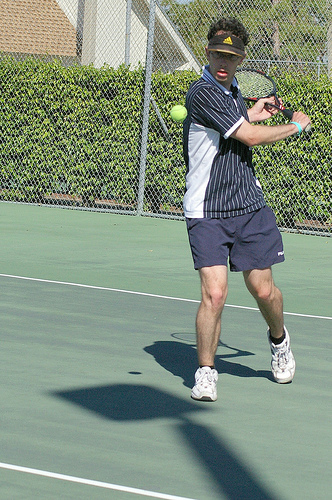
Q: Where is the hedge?
A: Behind the fence.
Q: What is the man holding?
A: A racket.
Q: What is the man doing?
A: Playing tennis?.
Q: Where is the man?
A: Tennis court.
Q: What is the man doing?
A: Hitting the ball.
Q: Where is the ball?
A: In the air.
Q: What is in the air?
A: The ball.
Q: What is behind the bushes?
A: A house.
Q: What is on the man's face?
A: Glasses.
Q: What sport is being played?
A: Tennis.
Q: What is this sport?
A: Tennis.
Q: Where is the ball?
A: In the air.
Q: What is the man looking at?
A: The ball.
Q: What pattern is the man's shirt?
A: Stripes.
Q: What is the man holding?
A: Tennis racket.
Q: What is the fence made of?
A: Metal.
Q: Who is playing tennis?
A: A man.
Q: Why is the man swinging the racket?
A: He is preparing to hit the tennis ball.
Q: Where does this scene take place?
A: On a tennis court.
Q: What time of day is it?
A: Daytime.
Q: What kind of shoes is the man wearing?
A: Tennis shoes.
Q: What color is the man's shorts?
A: Blue.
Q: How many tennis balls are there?
A: One.